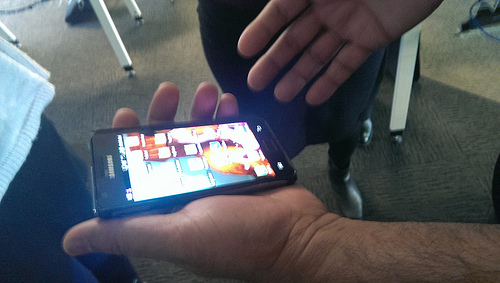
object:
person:
[188, 0, 398, 219]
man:
[63, 0, 500, 283]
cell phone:
[79, 112, 309, 221]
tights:
[324, 116, 361, 179]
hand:
[61, 71, 349, 267]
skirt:
[199, 0, 395, 164]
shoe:
[323, 148, 367, 221]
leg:
[361, 28, 425, 147]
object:
[347, 18, 428, 137]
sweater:
[3, 24, 57, 205]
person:
[0, 35, 138, 283]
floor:
[0, 0, 500, 220]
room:
[0, 0, 500, 283]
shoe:
[44, 0, 114, 29]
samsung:
[100, 149, 119, 182]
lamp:
[0, 1, 45, 23]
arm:
[259, 212, 500, 283]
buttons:
[242, 114, 310, 185]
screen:
[116, 121, 279, 202]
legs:
[79, 1, 148, 77]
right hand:
[209, 1, 449, 103]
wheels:
[120, 68, 142, 79]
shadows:
[54, 74, 154, 149]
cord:
[449, 0, 500, 46]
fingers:
[303, 42, 375, 105]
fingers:
[146, 77, 182, 125]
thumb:
[57, 211, 174, 260]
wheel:
[386, 130, 407, 147]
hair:
[338, 233, 500, 282]